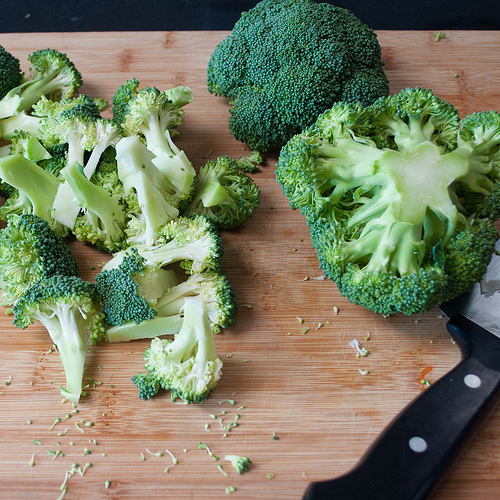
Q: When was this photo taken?
A: During cooking prep.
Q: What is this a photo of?
A: Broccoli.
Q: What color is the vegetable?
A: Green.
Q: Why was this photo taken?
A: To show the food.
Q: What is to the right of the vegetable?
A: A knife.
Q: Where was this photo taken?
A: In the kitchen.